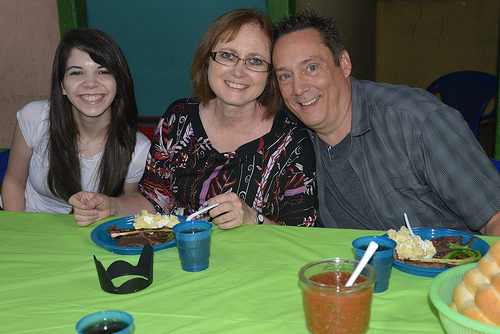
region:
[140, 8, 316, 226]
Woman wearing multi colored shirt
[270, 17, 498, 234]
Man wearing checkered shirt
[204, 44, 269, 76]
Eyeglasses on woman's face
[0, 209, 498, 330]
Green tablecloth on table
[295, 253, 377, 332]
Bowl of salsa on table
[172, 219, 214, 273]
Blue cup on table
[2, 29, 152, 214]
Woman wearing white shirt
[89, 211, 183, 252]
Blue plate on table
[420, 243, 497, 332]
Bowl of bread on table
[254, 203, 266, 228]
Watch on woman's wrist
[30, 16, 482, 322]
A family is eating together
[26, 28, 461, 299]
The family is having a meal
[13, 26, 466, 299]
The family is celebrating something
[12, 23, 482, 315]
The family is all together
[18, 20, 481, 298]
The family is at the table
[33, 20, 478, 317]
The family is eating their food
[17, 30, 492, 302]
A family is having their lunch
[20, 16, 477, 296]
A father is with his family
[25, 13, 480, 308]
A daughter is with her parents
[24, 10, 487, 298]
Everyone is smiling very happily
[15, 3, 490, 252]
Three people posing for a picture.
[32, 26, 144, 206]
The girl with long dark hair.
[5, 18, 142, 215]
A girl wearing a white shirt.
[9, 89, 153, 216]
A wide short sleeved shirt.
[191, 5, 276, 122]
A woman with red hair.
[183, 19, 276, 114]
A woman wearing glasses.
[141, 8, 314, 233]
A woman wearing a black multicolored top.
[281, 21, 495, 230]
A man wearing a grey shirt.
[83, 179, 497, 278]
Two plates of food.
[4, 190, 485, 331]
A green tablecloth.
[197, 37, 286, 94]
lady wearing black rimmed glasses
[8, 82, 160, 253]
lady wearing white top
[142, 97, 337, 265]
lady wearing black floral top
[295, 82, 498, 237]
man wearing grey shirt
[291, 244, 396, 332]
salsa on table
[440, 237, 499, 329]
bread rolls in a basket on table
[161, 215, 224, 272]
small blue cup with juice on table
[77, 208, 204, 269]
plate of food on table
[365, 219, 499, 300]
blue plate of food on table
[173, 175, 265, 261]
lady holding white plastic spoon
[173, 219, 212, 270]
blue beverage cup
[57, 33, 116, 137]
woman with a large smile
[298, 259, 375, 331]
jar of salsa on the table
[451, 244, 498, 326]
loaf of bread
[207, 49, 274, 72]
black eye glasses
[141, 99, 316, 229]
black shirt on woman's shirt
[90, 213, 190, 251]
blue plate full of food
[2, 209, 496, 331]
green table cloth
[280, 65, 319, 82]
man has blue eyes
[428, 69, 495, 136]
blue plastic chair